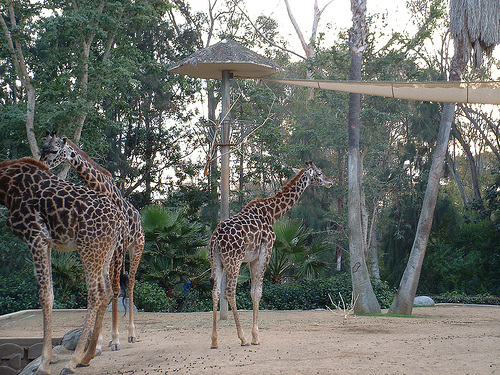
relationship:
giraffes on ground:
[7, 138, 333, 360] [18, 293, 499, 375]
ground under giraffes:
[18, 293, 499, 375] [7, 138, 333, 360]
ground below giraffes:
[18, 293, 499, 375] [7, 138, 333, 360]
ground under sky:
[18, 293, 499, 375] [6, 2, 499, 185]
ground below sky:
[18, 293, 499, 375] [6, 2, 499, 185]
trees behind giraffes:
[0, 3, 468, 295] [7, 138, 333, 360]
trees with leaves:
[0, 3, 468, 295] [53, 33, 143, 106]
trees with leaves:
[0, 3, 468, 295] [141, 25, 201, 155]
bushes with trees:
[0, 189, 410, 315] [0, 3, 468, 295]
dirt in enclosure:
[257, 306, 407, 370] [2, 304, 483, 373]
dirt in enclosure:
[0, 306, 499, 374] [5, 120, 481, 372]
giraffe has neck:
[205, 155, 342, 354] [255, 169, 313, 224]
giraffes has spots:
[7, 138, 333, 360] [19, 162, 132, 243]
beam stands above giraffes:
[218, 69, 235, 319] [7, 138, 333, 360]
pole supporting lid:
[212, 68, 245, 218] [168, 38, 283, 78]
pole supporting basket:
[212, 68, 245, 218] [183, 103, 258, 225]